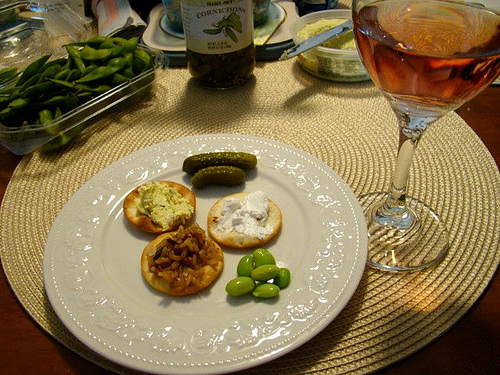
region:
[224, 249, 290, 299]
Six green lima beans on a plate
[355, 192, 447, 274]
Clear round wine glass base partially under a white plate.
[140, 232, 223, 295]
An orange colored round cracker with brown rice on top.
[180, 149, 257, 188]
Two green pickles on a plate.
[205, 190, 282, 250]
Tan and brown cracker with white substance on top.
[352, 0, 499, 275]
Amber colored glass of wine sitting next to a white plate.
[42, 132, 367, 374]
A round white shiny plate with crackers, beans and pickles on top.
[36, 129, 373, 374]
food on white plate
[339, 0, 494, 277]
a glass of wine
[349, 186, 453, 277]
a base of the glass wine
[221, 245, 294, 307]
beans on plate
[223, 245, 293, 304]
beans on white plate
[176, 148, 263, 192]
two pickles on plate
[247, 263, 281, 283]
green bean next to the beans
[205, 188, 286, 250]
a cracker with cheese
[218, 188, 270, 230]
cheese on cracker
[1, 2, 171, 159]
green beans on container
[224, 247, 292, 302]
six lime green lima beans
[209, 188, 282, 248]
golden cracker with cream cheese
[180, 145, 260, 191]
two small green pickles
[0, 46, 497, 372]
light tan circular placemat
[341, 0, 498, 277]
wine in a wine glass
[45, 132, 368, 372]
circle white dinner plate with food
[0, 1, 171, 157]
plastic container filled with snap peas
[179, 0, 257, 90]
glass jar of pickles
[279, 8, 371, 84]
knife laying on top of plastic tub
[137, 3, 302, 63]
two stacked white plates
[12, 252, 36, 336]
a mat on a table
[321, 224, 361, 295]
a design on a plate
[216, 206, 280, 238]
a cracker on a plate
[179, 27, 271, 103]
a bottle on the mat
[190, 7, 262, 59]
a label on a bottle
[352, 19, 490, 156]
wine in a glass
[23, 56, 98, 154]
beans in a container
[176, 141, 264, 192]
pickles on a plate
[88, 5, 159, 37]
paper on the table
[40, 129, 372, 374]
a white plate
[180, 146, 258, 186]
pickles on side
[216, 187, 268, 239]
white sauce on cracker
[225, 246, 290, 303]
green beans on plate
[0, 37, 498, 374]
a mat under the plate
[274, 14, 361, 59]
butter knife on top of container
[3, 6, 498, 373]
all food on the table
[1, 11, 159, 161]
the snap bean in trey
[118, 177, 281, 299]
three crackers on plate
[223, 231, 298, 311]
the food is green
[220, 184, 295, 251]
the food is white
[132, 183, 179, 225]
the food is yellow